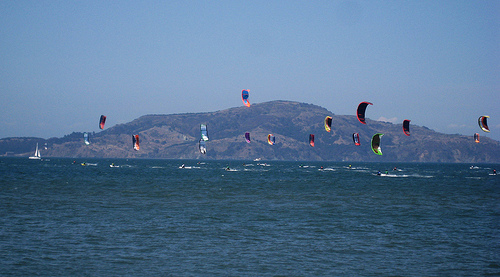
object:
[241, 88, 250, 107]
kite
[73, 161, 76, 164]
person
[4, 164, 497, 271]
water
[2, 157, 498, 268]
surface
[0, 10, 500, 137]
sky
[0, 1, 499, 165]
background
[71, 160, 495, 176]
people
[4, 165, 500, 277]
ocean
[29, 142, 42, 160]
boat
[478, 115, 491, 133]
kites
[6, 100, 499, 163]
land mass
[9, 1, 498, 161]
distance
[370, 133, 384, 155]
kite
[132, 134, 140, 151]
kite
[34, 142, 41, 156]
sailboat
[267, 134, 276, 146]
kite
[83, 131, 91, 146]
kite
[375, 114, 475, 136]
cloud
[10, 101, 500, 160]
hill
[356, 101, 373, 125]
c-kites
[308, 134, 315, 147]
kite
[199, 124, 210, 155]
c-kite